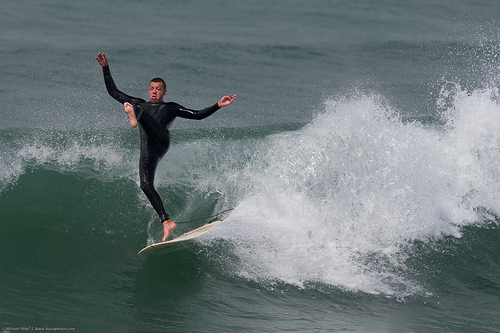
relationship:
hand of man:
[217, 93, 236, 107] [95, 50, 239, 242]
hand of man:
[94, 51, 110, 66] [95, 50, 239, 242]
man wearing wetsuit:
[95, 50, 239, 242] [103, 65, 223, 220]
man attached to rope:
[95, 50, 239, 242] [172, 207, 235, 224]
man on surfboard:
[95, 50, 239, 242] [138, 218, 222, 256]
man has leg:
[95, 50, 239, 242] [124, 101, 169, 150]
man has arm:
[95, 50, 239, 242] [102, 65, 145, 105]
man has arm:
[95, 50, 239, 242] [172, 102, 220, 119]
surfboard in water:
[138, 218, 222, 256] [1, 1, 500, 332]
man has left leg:
[95, 50, 239, 242] [138, 149, 176, 242]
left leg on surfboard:
[138, 149, 176, 242] [138, 218, 222, 256]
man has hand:
[95, 50, 239, 242] [94, 51, 110, 66]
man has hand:
[95, 50, 239, 242] [217, 93, 236, 107]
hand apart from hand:
[94, 51, 110, 66] [217, 93, 236, 107]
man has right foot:
[95, 50, 239, 242] [123, 101, 139, 130]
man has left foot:
[95, 50, 239, 242] [161, 220, 176, 240]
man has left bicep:
[95, 50, 239, 242] [179, 105, 195, 115]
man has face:
[95, 50, 239, 242] [149, 79, 163, 101]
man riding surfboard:
[95, 50, 239, 242] [138, 218, 222, 256]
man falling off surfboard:
[95, 50, 239, 242] [138, 218, 222, 256]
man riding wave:
[95, 50, 239, 242] [0, 2, 499, 306]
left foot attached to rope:
[161, 220, 176, 240] [172, 207, 235, 224]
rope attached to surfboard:
[172, 207, 235, 224] [138, 218, 222, 256]